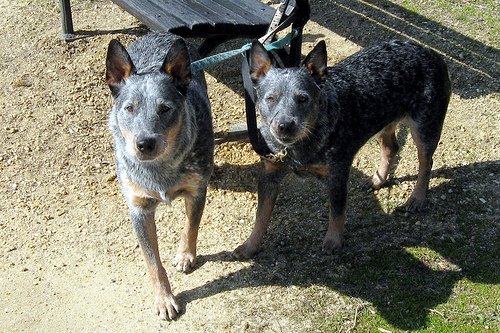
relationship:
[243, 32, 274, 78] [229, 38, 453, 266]
ear of dog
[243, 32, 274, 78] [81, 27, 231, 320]
ear of dog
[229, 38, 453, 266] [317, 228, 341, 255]
dog of foot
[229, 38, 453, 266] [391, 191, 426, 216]
dog of foot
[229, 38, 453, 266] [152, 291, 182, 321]
dog of foot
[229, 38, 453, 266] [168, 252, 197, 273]
dog of foot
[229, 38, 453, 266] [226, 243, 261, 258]
dog of foot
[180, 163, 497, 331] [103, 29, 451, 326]
shadow of dogs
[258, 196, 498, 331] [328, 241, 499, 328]
grassy area in right corner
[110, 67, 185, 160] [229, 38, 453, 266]
face looking forward dog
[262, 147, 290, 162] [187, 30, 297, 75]
hook on leash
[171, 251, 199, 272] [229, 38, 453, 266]
foot on dog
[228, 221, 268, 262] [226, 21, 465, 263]
foot on dog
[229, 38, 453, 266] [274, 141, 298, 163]
dog wearing collar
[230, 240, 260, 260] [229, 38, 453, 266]
paw of dog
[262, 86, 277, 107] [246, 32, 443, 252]
eye of dog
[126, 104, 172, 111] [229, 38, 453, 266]
dogs eyes of dog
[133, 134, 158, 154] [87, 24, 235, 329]
nose of dog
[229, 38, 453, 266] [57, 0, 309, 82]
dog tied to bench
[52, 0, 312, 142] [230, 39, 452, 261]
bench behind dogs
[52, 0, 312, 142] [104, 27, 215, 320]
bench behind dogs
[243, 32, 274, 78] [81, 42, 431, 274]
ear of dog